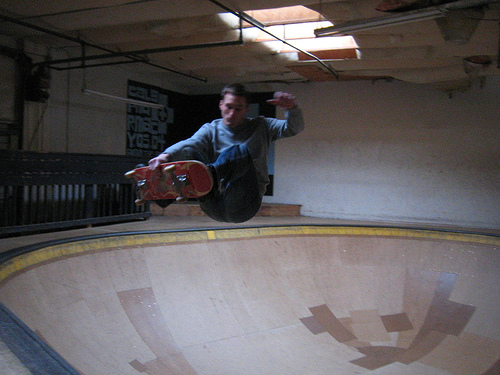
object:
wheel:
[125, 170, 138, 179]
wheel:
[135, 198, 146, 206]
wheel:
[163, 164, 176, 172]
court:
[3, 212, 497, 373]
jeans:
[181, 146, 261, 224]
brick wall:
[275, 76, 500, 231]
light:
[217, 6, 362, 65]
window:
[217, 4, 362, 61]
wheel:
[175, 195, 188, 203]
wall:
[53, 56, 132, 147]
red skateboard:
[123, 160, 214, 206]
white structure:
[255, 260, 302, 304]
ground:
[151, 211, 191, 230]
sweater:
[160, 103, 307, 197]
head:
[218, 83, 251, 129]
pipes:
[33, 39, 244, 67]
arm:
[264, 105, 305, 138]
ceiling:
[0, 2, 498, 90]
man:
[135, 84, 307, 224]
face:
[219, 93, 249, 128]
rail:
[1, 152, 152, 237]